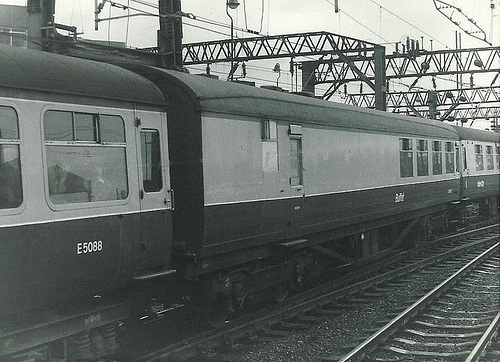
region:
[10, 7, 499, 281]
train cars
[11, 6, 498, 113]
electrical wires above a train car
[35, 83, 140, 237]
one clear glass window on the side of a train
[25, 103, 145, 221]
one clear glass window on the side of a train with passengers inside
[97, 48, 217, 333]
Connection between two train cars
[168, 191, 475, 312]
the bottom part of a train car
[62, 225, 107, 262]
Numbers on the side of a train car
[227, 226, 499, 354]
railway tracks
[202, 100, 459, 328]
the side of a train car on railway tracks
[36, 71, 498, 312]
The side of a train on railway tracks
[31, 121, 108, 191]
People inside the train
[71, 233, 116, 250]
Number of train on the side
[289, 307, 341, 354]
Gravel between the tracks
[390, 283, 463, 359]
The tracks are somewhat rusty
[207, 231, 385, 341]
Wheels under the train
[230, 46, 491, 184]
Metal scaffolding above the train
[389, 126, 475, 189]
Windows on side of train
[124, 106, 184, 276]
Dress on side of train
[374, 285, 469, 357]
Light shining on the track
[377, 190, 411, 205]
Number on side of train car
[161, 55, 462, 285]
one passenger train car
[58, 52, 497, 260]
three passenger train cars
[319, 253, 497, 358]
silver train tracks on gravel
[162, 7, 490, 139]
overhead structure and wiring at train yard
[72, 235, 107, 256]
serial number E5088 on train car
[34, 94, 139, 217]
window of passenger train car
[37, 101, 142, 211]
girl in window of train car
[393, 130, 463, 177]
four passenger train car windows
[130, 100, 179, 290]
passenger train car door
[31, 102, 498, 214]
windows of passenger train cars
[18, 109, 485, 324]
light and dark train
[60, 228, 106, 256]
white serial number on train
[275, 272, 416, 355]
dark gravel between tracks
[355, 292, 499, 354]
dark tracks near train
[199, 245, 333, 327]
train has black wheels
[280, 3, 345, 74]
sky is grey and cloudy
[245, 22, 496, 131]
power lines over train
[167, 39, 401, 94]
metal beams over train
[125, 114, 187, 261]
grey and black door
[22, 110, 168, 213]
train has rectangular windows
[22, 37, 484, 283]
A grey and white train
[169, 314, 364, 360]
A metalic train truck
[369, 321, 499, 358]
A metalic train truck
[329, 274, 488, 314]
A metalic train truck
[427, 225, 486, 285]
A metalic train truck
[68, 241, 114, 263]
A black and white train number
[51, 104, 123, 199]
A black and white train's window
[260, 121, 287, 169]
A black and white train's window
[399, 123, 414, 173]
A black and white train's window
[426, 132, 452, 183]
A black and white train's window